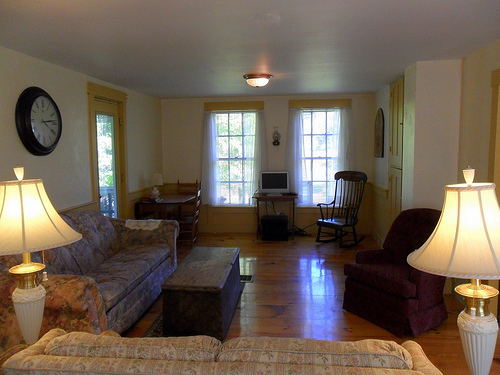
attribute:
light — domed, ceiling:
[241, 72, 271, 88]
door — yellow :
[365, 68, 417, 238]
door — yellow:
[381, 70, 407, 249]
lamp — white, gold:
[406, 166, 498, 373]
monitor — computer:
[255, 165, 290, 195]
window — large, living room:
[200, 101, 261, 209]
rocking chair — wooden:
[313, 168, 369, 248]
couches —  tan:
[1, 327, 443, 374]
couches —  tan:
[2, 202, 179, 332]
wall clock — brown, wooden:
[6, 73, 79, 170]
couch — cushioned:
[34, 200, 162, 331]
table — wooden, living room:
[157, 217, 264, 335]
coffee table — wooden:
[157, 241, 244, 341]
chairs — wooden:
[142, 158, 222, 223]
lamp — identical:
[395, 169, 498, 358]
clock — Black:
[14, 83, 63, 158]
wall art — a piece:
[372, 107, 385, 157]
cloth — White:
[120, 211, 164, 237]